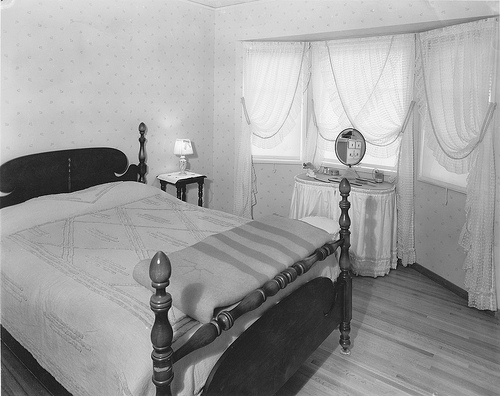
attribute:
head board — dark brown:
[3, 115, 147, 213]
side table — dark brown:
[152, 169, 210, 205]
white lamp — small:
[174, 136, 193, 179]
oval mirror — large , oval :
[326, 120, 370, 171]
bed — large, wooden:
[5, 129, 368, 381]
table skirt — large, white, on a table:
[288, 157, 405, 279]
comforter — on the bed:
[82, 175, 322, 344]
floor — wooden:
[383, 299, 442, 370]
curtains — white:
[287, 50, 394, 91]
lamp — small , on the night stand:
[165, 127, 215, 199]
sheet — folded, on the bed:
[60, 212, 179, 316]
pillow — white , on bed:
[60, 182, 150, 217]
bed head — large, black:
[35, 133, 180, 172]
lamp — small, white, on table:
[156, 130, 201, 204]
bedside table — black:
[157, 147, 203, 225]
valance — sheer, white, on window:
[222, 50, 429, 164]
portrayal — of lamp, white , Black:
[155, 110, 226, 202]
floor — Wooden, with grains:
[374, 297, 456, 384]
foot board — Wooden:
[115, 243, 404, 364]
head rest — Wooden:
[3, 136, 156, 201]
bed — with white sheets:
[4, 118, 364, 361]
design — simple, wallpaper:
[19, 14, 175, 123]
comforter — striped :
[132, 204, 342, 309]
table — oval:
[289, 160, 401, 203]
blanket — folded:
[134, 214, 356, 316]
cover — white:
[8, 177, 199, 372]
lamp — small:
[165, 133, 205, 178]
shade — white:
[169, 133, 202, 156]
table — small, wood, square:
[160, 169, 213, 206]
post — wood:
[327, 177, 363, 356]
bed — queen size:
[15, 136, 385, 387]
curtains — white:
[217, 28, 484, 316]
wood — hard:
[345, 285, 484, 385]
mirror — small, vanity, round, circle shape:
[329, 128, 371, 170]